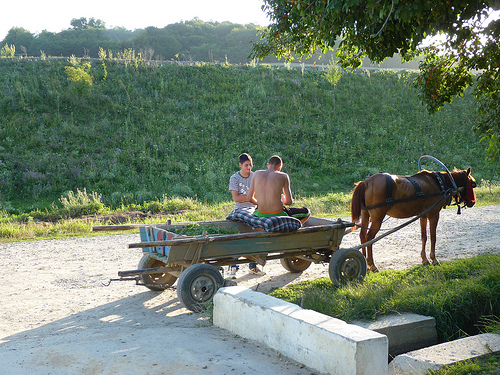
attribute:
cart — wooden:
[122, 207, 360, 295]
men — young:
[214, 141, 316, 226]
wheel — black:
[176, 264, 228, 315]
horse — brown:
[344, 163, 481, 267]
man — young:
[244, 150, 309, 227]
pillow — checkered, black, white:
[224, 202, 304, 237]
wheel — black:
[329, 249, 367, 289]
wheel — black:
[281, 251, 313, 274]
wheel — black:
[133, 256, 179, 291]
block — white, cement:
[205, 266, 397, 371]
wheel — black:
[173, 264, 235, 314]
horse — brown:
[365, 135, 480, 257]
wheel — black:
[176, 265, 223, 312]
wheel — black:
[176, 269, 213, 306]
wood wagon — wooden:
[80, 218, 385, 306]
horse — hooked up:
[353, 165, 472, 263]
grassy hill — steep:
[2, 57, 499, 237]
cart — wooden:
[87, 208, 367, 308]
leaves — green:
[255, 4, 496, 162]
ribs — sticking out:
[398, 175, 434, 199]